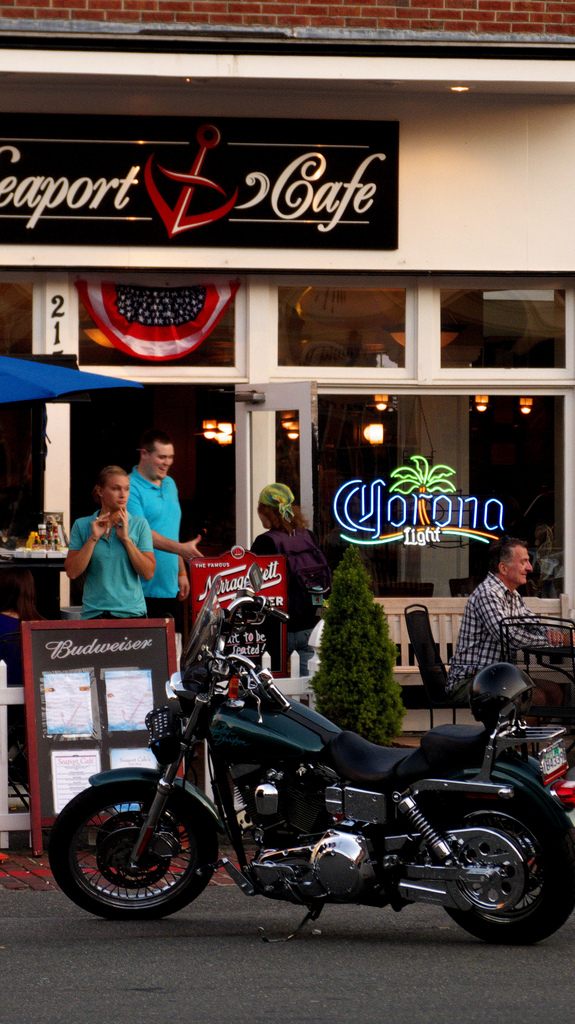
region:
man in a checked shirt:
[444, 533, 568, 744]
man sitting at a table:
[441, 526, 571, 732]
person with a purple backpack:
[241, 476, 336, 680]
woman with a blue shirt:
[62, 461, 163, 639]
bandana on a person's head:
[256, 477, 299, 523]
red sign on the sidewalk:
[181, 541, 293, 688]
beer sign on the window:
[324, 446, 517, 556]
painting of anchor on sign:
[135, 116, 245, 242]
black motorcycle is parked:
[32, 558, 573, 961]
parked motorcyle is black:
[41, 561, 574, 951]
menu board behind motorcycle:
[14, 611, 201, 858]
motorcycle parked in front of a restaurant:
[41, 581, 573, 953]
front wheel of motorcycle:
[41, 752, 229, 935]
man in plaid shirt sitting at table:
[404, 536, 573, 699]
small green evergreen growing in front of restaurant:
[307, 537, 404, 749]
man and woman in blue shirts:
[59, 431, 210, 630]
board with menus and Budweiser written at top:
[6, 609, 190, 843]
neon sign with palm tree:
[316, 437, 507, 569]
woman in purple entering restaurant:
[243, 471, 321, 681]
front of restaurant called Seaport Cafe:
[0, 63, 573, 661]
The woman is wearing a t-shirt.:
[64, 465, 152, 620]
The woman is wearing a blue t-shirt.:
[62, 466, 157, 614]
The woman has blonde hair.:
[92, 463, 132, 512]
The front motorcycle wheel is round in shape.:
[48, 781, 218, 925]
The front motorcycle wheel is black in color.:
[47, 780, 220, 923]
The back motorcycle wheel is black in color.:
[414, 795, 573, 947]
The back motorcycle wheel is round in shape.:
[422, 800, 571, 941]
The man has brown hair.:
[138, 435, 178, 481]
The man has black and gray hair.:
[491, 537, 532, 586]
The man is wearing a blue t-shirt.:
[126, 431, 202, 597]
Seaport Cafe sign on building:
[1, 116, 398, 247]